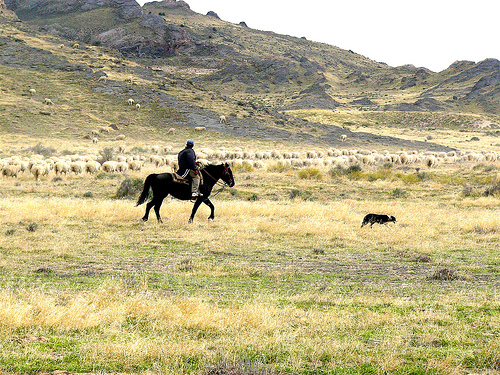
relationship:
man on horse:
[176, 132, 208, 202] [134, 160, 238, 224]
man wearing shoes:
[176, 139, 207, 197] [191, 190, 206, 197]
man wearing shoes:
[176, 139, 207, 197] [188, 185, 205, 202]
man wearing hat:
[176, 132, 208, 202] [185, 140, 194, 145]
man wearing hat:
[176, 139, 207, 197] [184, 138, 196, 148]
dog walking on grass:
[350, 201, 384, 228] [20, 245, 499, 369]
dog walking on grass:
[360, 212, 398, 228] [1, 133, 497, 370]